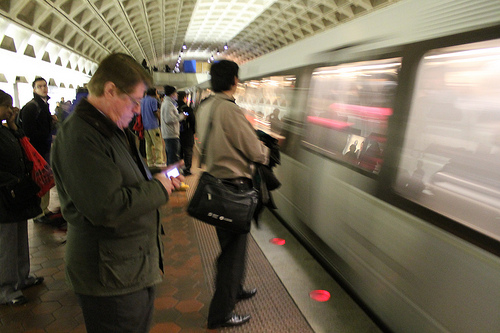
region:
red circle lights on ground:
[271, 234, 355, 325]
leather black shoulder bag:
[188, 162, 275, 235]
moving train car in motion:
[253, 32, 493, 162]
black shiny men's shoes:
[207, 290, 276, 329]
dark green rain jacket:
[56, 116, 212, 301]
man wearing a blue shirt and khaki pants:
[142, 92, 189, 171]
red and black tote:
[2, 124, 86, 213]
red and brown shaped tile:
[169, 248, 185, 317]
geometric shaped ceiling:
[90, 17, 299, 42]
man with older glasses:
[100, 82, 151, 108]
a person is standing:
[180, 29, 277, 326]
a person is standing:
[53, 47, 189, 329]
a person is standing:
[158, 82, 190, 168]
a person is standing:
[173, 82, 205, 197]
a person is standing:
[140, 77, 165, 168]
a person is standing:
[22, 69, 58, 231]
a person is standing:
[0, 91, 47, 321]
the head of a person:
[81, 45, 151, 127]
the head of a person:
[203, 52, 244, 95]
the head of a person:
[27, 75, 54, 102]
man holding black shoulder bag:
[186, 57, 281, 329]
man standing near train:
[192, 57, 291, 324]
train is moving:
[188, 0, 498, 330]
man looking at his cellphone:
[53, 52, 189, 331]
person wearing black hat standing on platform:
[160, 84, 192, 171]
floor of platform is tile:
[18, 147, 315, 331]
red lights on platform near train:
[309, 287, 333, 301]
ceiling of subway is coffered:
[0, 2, 399, 78]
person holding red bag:
[0, 90, 48, 309]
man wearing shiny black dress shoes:
[227, 312, 252, 325]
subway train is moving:
[190, 2, 498, 332]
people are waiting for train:
[0, 50, 284, 332]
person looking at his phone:
[166, 167, 181, 182]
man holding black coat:
[252, 128, 282, 230]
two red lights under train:
[267, 236, 330, 302]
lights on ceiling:
[172, 42, 229, 72]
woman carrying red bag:
[20, 136, 56, 198]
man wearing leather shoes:
[205, 282, 257, 324]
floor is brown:
[0, 156, 220, 331]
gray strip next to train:
[249, 204, 384, 331]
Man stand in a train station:
[181, 53, 284, 331]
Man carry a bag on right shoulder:
[179, 47, 288, 331]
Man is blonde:
[45, 42, 198, 331]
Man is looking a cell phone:
[45, 46, 201, 330]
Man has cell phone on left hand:
[48, 46, 198, 211]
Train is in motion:
[266, 0, 497, 332]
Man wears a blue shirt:
[139, 81, 169, 176]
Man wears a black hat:
[157, 81, 188, 169]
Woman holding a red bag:
[3, 91, 62, 313]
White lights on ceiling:
[166, 39, 234, 70]